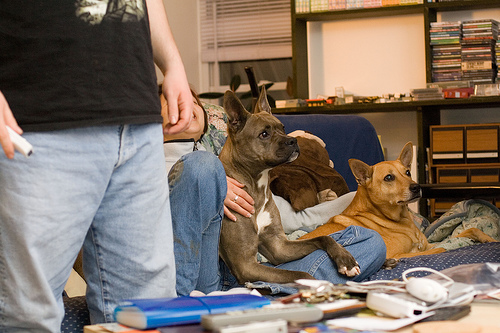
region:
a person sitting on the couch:
[157, 83, 385, 294]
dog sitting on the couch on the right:
[295, 140, 497, 258]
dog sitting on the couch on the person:
[217, 83, 360, 285]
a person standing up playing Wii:
[0, 0, 192, 332]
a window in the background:
[197, 0, 293, 107]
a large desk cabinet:
[270, 0, 499, 231]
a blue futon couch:
[0, 113, 499, 332]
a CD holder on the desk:
[428, 121, 498, 167]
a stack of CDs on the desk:
[428, 20, 461, 81]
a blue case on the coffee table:
[112, 293, 269, 330]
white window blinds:
[198, 0, 293, 59]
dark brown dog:
[215, 81, 365, 288]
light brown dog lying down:
[296, 135, 493, 255]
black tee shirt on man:
[0, 0, 169, 133]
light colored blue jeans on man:
[1, 106, 177, 329]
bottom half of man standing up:
[2, 1, 197, 331]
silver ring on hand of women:
[232, 192, 239, 205]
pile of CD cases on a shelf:
[429, 17, 499, 84]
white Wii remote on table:
[342, 262, 463, 319]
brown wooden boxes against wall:
[427, 120, 498, 190]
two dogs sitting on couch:
[173, 98, 458, 275]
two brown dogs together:
[152, 83, 429, 305]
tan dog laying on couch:
[325, 122, 431, 262]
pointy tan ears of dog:
[333, 133, 423, 182]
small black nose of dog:
[403, 174, 420, 199]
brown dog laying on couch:
[181, 79, 334, 297]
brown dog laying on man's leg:
[190, 93, 381, 297]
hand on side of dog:
[212, 169, 263, 237]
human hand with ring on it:
[201, 175, 265, 225]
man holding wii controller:
[0, 0, 200, 235]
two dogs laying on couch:
[161, 71, 446, 262]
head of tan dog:
[338, 138, 423, 206]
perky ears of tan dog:
[341, 134, 429, 184]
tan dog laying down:
[307, 135, 440, 259]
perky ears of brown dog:
[192, 77, 274, 125]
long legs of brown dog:
[235, 223, 353, 294]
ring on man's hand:
[211, 176, 261, 216]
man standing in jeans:
[0, 0, 208, 322]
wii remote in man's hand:
[0, 91, 40, 166]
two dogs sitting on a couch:
[225, 78, 433, 285]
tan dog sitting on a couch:
[337, 150, 446, 259]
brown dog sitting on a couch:
[217, 70, 312, 277]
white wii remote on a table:
[352, 253, 457, 323]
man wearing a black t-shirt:
[9, 1, 189, 306]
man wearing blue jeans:
[22, 3, 189, 316]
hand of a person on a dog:
[206, 158, 281, 235]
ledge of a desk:
[272, 79, 498, 119]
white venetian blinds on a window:
[201, 9, 295, 105]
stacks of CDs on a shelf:
[430, 15, 496, 100]